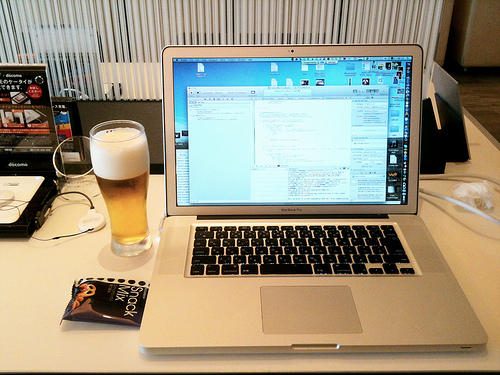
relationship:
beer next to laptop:
[84, 120, 156, 260] [138, 43, 489, 355]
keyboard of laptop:
[190, 225, 416, 276] [138, 43, 489, 355]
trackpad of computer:
[249, 277, 374, 342] [114, 23, 497, 368]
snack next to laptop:
[56, 271, 151, 348] [138, 43, 489, 355]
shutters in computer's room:
[0, 0, 442, 102] [0, 0, 500, 369]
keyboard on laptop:
[215, 191, 419, 292] [119, 20, 453, 357]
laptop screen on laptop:
[172, 55, 415, 208] [132, 41, 491, 361]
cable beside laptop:
[419, 173, 500, 227] [132, 41, 491, 361]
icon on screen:
[266, 61, 282, 73] [172, 57, 406, 207]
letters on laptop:
[271, 206, 306, 218] [138, 43, 489, 355]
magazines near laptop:
[2, 58, 83, 168] [132, 41, 491, 361]